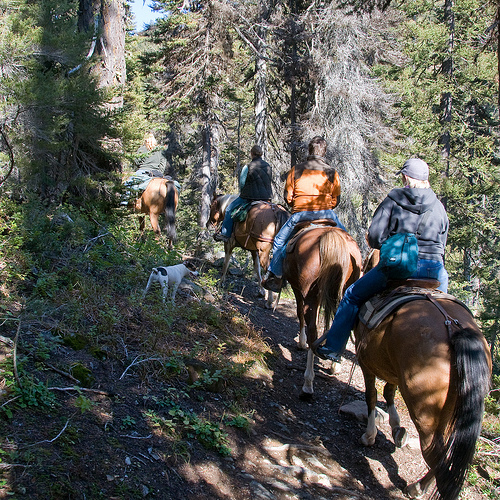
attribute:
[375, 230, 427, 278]
bag — blue, green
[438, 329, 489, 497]
tail — black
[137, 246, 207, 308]
dog — white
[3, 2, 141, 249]
trees — green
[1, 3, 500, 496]
woods — wooded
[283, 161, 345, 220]
jacket — orange, black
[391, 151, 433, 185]
cap — gray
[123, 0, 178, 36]
sky — blue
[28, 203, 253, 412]
grass — green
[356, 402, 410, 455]
hooves — white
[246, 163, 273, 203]
vest — black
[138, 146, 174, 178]
jacket — green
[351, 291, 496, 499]
horse — brown